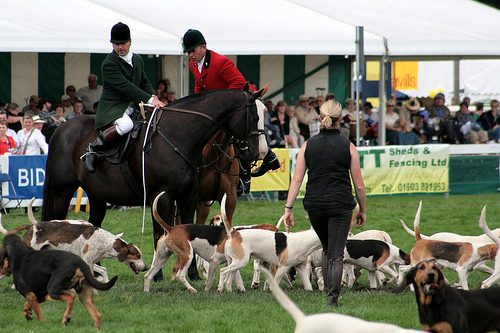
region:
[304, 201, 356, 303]
Woman wearing pants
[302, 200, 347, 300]
Woman is wearing pants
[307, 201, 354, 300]
Woman wearing black pants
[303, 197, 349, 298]
Woman is wearing black pants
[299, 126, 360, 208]
Woman wearing a shirt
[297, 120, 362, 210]
Woman is wearing a shirt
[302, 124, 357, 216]
Woman wearing a black shirt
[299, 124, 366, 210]
Woman is wearing a black shirt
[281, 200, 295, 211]
Woman wearing a bracelet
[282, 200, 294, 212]
Woman is wearing a bracelet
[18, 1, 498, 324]
a hunting show with a dogs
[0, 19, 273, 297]
these riders are running with dogs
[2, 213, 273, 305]
hunting dogs on the grounds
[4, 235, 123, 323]
a black hunting dog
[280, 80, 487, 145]
spectators in the stands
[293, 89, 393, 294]
the lady walking toward the dog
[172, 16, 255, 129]
this guy is looking at the dogs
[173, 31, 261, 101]
this rider has on a red coat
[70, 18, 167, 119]
this rider has on a green coat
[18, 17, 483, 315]
this is part of a esquarian event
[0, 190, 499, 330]
many dogs on a lawn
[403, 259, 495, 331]
a black and brown dog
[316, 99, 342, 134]
a woman with blonde hair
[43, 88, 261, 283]
a dark brown horse on a lawn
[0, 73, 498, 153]
spectators watching a dog show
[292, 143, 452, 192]
a yellow and green advertisement on a fence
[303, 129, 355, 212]
woman wearing a black vest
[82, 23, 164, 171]
a man riding a horse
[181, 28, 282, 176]
a man propping himself on a horse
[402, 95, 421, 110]
person wearing a cowboy hat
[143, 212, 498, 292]
beagles gathering for a hunt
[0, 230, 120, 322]
bloodhound that will participate in the hunt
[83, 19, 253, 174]
hunters assembling for a fox hunt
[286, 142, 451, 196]
advertiser for the big hunt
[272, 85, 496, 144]
spectators have gathered for the beginning of the hunt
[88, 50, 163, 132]
this rider is wearing a forest green jacket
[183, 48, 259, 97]
this rider is wearing a red jacket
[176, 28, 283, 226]
a rider mounting his steed for the hunt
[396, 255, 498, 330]
a dog getting ready to participate in the hunt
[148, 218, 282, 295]
beagles are typically white, brown, and black